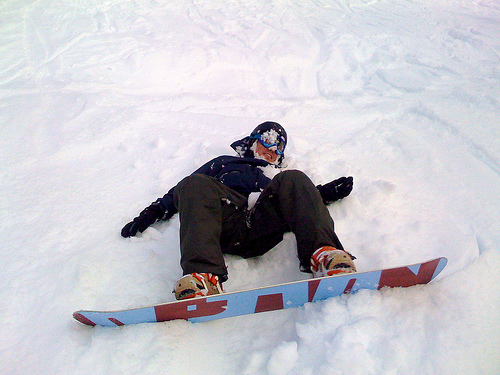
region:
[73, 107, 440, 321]
a person laying in the snow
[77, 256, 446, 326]
a red and white snow board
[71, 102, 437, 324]
a snowboarder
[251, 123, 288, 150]
blue goggles on the person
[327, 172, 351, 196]
a glove on the persons hand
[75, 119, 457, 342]
a person fallen in the snow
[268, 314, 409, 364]
snow on the ground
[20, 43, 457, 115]
tracks in the snow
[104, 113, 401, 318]
a person wearing a coat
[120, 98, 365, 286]
a person wearing a snow cap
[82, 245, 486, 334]
snowboard is blue and red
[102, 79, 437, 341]
snowboarder laying in the snow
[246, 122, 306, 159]
snow on the goggles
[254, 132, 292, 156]
goggles are blue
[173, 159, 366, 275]
snowboarder's pants are black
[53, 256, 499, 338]
snowboard is on it's side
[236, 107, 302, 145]
snowboarder is wearing a hat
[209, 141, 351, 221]
snow on the jacket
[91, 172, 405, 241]
snow gloves are black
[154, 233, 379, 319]
snowboard buckles are red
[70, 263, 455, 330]
A snowboard colored red and light blue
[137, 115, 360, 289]
A man dressed in winter gear laying on his back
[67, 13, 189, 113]
An area of white slightly marked snow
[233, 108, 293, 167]
A man with snow-spattered goggles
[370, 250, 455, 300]
The tip of a snowboard with a geographic design on its bottom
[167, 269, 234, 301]
A man's right foot with a ski boot on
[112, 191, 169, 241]
A man's right hand wearing a black mitten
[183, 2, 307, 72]
A section of snow with tracks running across it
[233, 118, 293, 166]
A man's face, slightly grinning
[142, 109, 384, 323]
A snowboarder lying on his back in the snow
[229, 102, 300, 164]
head of a person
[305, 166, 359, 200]
hand of a person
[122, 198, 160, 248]
hand of a person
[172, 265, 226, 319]
leg of a person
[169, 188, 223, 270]
leg of a person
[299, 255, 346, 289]
feet of a person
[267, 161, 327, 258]
leg of a person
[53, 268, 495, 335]
snowboard on a snow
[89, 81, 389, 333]
person wearing a hat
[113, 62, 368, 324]
person wearing a jacket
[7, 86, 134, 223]
snow on the ground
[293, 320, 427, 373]
tracks in the snow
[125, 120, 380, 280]
a man laying in the snow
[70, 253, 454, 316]
a man with a snowboard on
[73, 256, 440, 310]
a snowboard in the snow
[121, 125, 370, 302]
a person wearing blue goggles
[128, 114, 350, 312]
a person wearing a black jacket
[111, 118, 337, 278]
a person wearing black gloves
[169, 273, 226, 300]
the snow bood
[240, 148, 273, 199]
snow on the person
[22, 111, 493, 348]
this snowboarder skidded to a halt, fortunately on his back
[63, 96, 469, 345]
snowboard lying in the snow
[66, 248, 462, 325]
red and white snowboard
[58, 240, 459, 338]
red and white snowboard with bindings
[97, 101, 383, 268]
snowboard wearing black snow suit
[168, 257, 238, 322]
binding and boot on snowboard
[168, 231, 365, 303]
boots in snowboard bindings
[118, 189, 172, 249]
glove on right hand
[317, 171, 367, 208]
glove on left hand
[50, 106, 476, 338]
lying on back in the snow